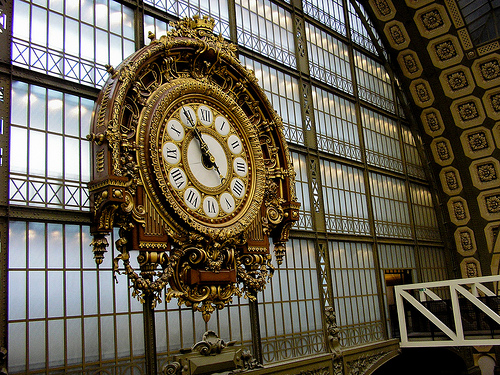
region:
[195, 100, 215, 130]
roman numeral on clock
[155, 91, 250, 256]
face of the clock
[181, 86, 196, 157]
minute hand of the clock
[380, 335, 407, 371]
arch of the wall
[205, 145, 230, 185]
hour hand of clock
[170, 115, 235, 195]
hands of the clock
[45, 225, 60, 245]
light on the wall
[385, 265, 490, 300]
wood railing of bannister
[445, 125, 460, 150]
dark space between designs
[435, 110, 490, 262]
designs on the wall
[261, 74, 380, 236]
large windows on the building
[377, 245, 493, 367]
white wooden structure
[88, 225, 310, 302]
design beneath the clock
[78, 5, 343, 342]
large golden clock on the wall of windows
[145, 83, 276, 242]
white and golden clock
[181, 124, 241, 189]
white circle in the clock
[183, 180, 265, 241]
small circles around the clock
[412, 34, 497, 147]
golden ceiling by the clock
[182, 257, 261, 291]
brown piece of the clock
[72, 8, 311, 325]
and old clock color gold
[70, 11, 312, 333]
clock is yellow and fancy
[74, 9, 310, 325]
clock has intricate designs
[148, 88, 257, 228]
clock has white numerals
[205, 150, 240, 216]
hour handle is in V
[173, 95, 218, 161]
minute is in XI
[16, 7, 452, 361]
window is in arch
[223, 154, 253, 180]
clock has number III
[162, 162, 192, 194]
clock has number VIII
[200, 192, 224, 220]
clock has number VI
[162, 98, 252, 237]
gold and white analog clock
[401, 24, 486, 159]
roman design on wall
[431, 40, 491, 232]
roman design on wall